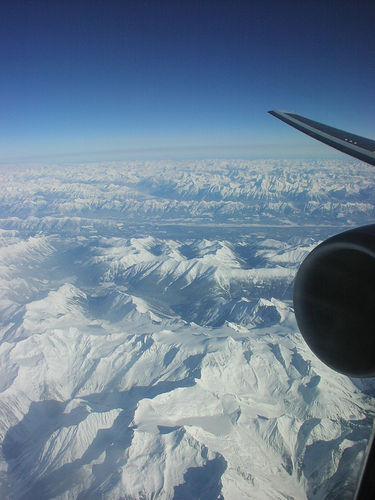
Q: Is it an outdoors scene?
A: Yes, it is outdoors.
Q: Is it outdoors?
A: Yes, it is outdoors.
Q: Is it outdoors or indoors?
A: It is outdoors.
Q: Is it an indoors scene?
A: No, it is outdoors.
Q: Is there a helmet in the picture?
A: No, there are no helmets.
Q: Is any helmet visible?
A: No, there are no helmets.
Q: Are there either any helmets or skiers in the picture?
A: No, there are no helmets or skiers.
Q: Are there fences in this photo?
A: No, there are no fences.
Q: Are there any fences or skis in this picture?
A: No, there are no fences or skis.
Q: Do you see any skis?
A: No, there are no skis.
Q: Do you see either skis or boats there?
A: No, there are no skis or boats.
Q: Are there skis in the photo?
A: No, there are no skis.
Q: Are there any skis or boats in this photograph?
A: No, there are no skis or boats.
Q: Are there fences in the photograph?
A: No, there are no fences.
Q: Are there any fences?
A: No, there are no fences.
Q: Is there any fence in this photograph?
A: No, there are no fences.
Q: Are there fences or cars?
A: No, there are no fences or cars.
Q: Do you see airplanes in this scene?
A: Yes, there is an airplane.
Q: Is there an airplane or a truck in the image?
A: Yes, there is an airplane.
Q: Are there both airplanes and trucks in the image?
A: No, there is an airplane but no trucks.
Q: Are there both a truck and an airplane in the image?
A: No, there is an airplane but no trucks.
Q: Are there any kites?
A: No, there are no kites.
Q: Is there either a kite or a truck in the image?
A: No, there are no kites or trucks.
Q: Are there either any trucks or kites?
A: No, there are no kites or trucks.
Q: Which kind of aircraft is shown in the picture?
A: The aircraft is an airplane.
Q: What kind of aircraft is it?
A: The aircraft is an airplane.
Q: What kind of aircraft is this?
A: This is an airplane.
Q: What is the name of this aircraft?
A: This is an airplane.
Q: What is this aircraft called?
A: This is an airplane.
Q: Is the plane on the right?
A: Yes, the plane is on the right of the image.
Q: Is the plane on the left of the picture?
A: No, the plane is on the right of the image.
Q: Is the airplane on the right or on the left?
A: The airplane is on the right of the image.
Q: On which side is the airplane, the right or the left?
A: The airplane is on the right of the image.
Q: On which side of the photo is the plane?
A: The plane is on the right of the image.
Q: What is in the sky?
A: The airplane is in the sky.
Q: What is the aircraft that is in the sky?
A: The aircraft is an airplane.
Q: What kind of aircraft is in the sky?
A: The aircraft is an airplane.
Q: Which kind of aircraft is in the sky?
A: The aircraft is an airplane.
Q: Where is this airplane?
A: The airplane is in the sky.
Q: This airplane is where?
A: The airplane is in the sky.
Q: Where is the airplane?
A: The airplane is in the sky.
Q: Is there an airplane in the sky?
A: Yes, there is an airplane in the sky.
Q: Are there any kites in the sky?
A: No, there is an airplane in the sky.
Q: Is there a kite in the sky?
A: No, there is an airplane in the sky.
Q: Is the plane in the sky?
A: Yes, the plane is in the sky.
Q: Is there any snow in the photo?
A: Yes, there is snow.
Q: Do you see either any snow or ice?
A: Yes, there is snow.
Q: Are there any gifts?
A: No, there are no gifts.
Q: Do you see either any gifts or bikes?
A: No, there are no gifts or bikes.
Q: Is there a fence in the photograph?
A: No, there are no fences.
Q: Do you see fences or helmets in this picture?
A: No, there are no fences or helmets.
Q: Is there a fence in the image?
A: No, there are no fences.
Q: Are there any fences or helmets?
A: No, there are no fences or helmets.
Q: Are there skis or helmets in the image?
A: No, there are no skis or helmets.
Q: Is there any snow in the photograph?
A: Yes, there is snow.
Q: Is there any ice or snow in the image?
A: Yes, there is snow.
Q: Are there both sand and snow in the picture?
A: No, there is snow but no sand.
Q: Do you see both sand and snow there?
A: No, there is snow but no sand.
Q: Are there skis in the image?
A: No, there are no skis.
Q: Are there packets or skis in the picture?
A: No, there are no skis or packets.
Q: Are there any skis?
A: No, there are no skis.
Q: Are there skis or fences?
A: No, there are no skis or fences.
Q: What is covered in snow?
A: The mountain peak is covered in snow.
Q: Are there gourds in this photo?
A: No, there are no gourds.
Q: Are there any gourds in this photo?
A: No, there are no gourds.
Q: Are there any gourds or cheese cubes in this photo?
A: No, there are no gourds or cheese cubes.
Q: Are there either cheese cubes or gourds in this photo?
A: No, there are no gourds or cheese cubes.